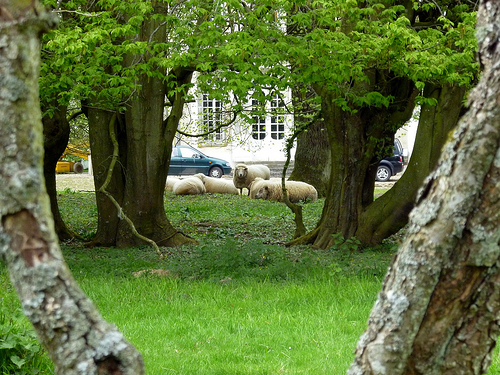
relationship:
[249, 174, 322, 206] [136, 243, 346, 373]
sheep on grass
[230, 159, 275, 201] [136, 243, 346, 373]
sheep on grass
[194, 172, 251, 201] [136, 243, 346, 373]
sheep on grass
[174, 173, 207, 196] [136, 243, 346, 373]
sheep on grass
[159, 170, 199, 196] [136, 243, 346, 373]
sheep on grass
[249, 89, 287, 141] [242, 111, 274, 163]
window on building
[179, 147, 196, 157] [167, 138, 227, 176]
car window on car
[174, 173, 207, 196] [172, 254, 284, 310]
sheep in grass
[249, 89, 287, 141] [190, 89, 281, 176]
window on building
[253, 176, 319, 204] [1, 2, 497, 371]
sheep in park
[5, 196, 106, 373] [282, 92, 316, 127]
tree with leaves